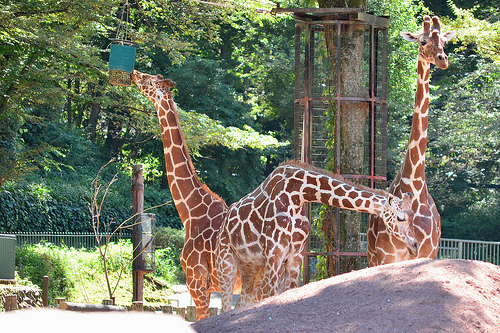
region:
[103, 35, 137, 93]
a hanging giraffe feeder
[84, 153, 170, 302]
a small bare leafless tree in a giraffe enclosure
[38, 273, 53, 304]
a small brown post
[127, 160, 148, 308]
a tall brown post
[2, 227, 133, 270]
a fence around a giraffe enclosure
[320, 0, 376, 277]
a brown tree trunk protected by a wraparound fence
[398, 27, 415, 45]
the ear of a giraffe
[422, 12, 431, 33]
a brown horn on a giraffe's head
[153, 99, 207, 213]
the long neck of a giraffe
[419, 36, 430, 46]
the eye of a giraffe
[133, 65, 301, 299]
Giraffe has long neck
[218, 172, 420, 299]
Giraffe has long neck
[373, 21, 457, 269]
Giraffe has long neck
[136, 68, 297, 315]
Giraffe has brown spots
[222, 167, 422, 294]
Giraffe has brown spots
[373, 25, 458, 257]
Giraffe has brown spots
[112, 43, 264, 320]
Giraffe eating from feeder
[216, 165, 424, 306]
Giraffe licking large rock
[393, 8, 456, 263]
Giraffe has two horns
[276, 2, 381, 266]
tree surrounded by cage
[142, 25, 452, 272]
three giraffes near each other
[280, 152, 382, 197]
giraffe has brown mane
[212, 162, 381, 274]
brown and white spots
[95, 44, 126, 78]
green cage with food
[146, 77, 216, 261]
giraffe has long neck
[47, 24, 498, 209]
green trees behind fence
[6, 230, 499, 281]
grey bars on fence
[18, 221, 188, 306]
green bushes in front of fence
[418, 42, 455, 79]
giraffe has brown nose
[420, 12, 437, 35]
giraffe has brown ossicles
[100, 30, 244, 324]
this giraffe is feeding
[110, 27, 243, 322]
this giraffe is eating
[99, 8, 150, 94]
this is a giraffe feeder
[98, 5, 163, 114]
the giraffe feeder is green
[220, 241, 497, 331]
this is a mound of dirt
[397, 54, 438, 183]
the long neck of a giraffe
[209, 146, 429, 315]
this giraffe has its neck down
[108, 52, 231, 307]
the giraffe is extending its head up to eat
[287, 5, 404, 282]
there is a fence around this tree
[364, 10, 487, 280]
this giraffe is standing up straight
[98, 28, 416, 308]
giraffes at the zoo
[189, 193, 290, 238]
spotted pattern on giraffe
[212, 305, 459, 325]
shadow on the rock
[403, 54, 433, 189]
neck of the giraffe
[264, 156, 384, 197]
mane of the giraffe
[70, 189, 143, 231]
the bushes are dense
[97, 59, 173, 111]
the giraffe is eating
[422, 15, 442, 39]
horns on the giraffe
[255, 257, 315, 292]
legs of the giraffe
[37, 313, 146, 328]
sand on the ground